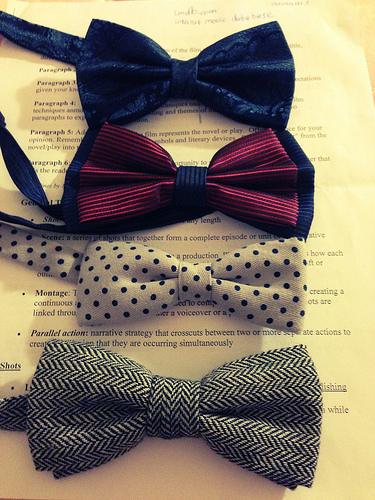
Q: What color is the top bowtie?
A: Blue.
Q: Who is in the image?
A: Nobody.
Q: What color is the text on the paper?
A: Black.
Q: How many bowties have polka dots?
A: One.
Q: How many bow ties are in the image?
A: Four.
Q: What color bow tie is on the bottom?
A: Black and white.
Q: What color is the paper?
A: White.